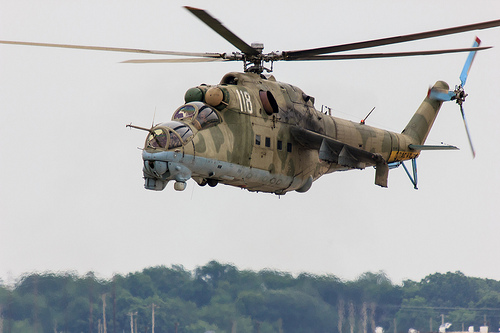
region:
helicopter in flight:
[46, 10, 470, 190]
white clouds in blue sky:
[35, 83, 80, 128]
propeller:
[54, 8, 461, 78]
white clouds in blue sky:
[9, 79, 62, 119]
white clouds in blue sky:
[29, 178, 103, 244]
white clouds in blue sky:
[111, 195, 183, 244]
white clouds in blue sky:
[216, 208, 288, 258]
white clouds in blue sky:
[271, 200, 330, 248]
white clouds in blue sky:
[321, 195, 401, 250]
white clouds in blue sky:
[411, 201, 458, 236]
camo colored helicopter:
[18, 9, 485, 216]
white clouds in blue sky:
[5, 53, 47, 105]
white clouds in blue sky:
[61, 52, 99, 119]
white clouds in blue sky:
[6, 98, 76, 162]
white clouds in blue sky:
[68, 103, 108, 152]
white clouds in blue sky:
[28, 153, 81, 208]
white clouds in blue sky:
[28, 214, 100, 248]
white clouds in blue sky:
[144, 204, 223, 250]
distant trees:
[183, 280, 238, 315]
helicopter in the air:
[48, 5, 484, 215]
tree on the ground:
[320, 270, 346, 325]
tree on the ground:
[248, 286, 285, 330]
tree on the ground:
[138, 293, 167, 327]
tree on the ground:
[89, 276, 117, 331]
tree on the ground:
[360, 271, 382, 328]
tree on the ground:
[438, 267, 468, 327]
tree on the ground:
[38, 267, 79, 321]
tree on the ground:
[51, 293, 82, 329]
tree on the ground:
[21, 283, 43, 328]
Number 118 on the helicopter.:
[234, 85, 255, 119]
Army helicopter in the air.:
[60, 12, 495, 188]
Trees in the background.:
[11, 257, 491, 322]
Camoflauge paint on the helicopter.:
[218, 128, 276, 160]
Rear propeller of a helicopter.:
[423, 27, 498, 152]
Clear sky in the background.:
[31, 106, 123, 248]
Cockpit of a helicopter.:
[170, 98, 222, 142]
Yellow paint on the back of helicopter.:
[384, 146, 417, 161]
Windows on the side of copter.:
[255, 132, 300, 155]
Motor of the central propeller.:
[242, 36, 272, 77]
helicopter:
[43, 4, 455, 204]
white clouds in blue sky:
[74, 176, 121, 222]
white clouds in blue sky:
[287, 205, 347, 257]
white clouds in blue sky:
[358, 219, 418, 266]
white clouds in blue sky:
[431, 197, 470, 265]